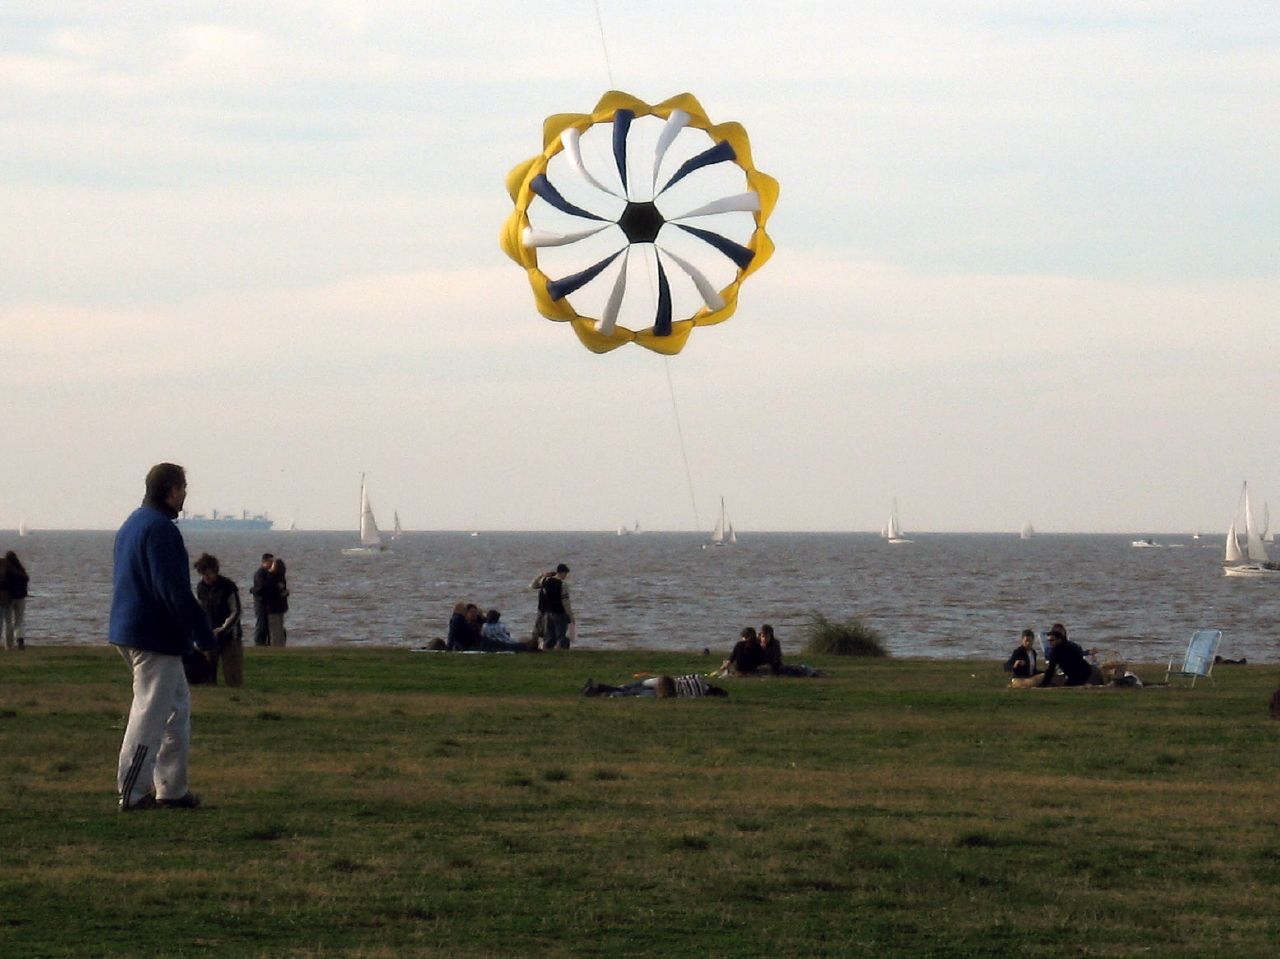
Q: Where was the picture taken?
A: On a beach.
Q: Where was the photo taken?
A: In a park.